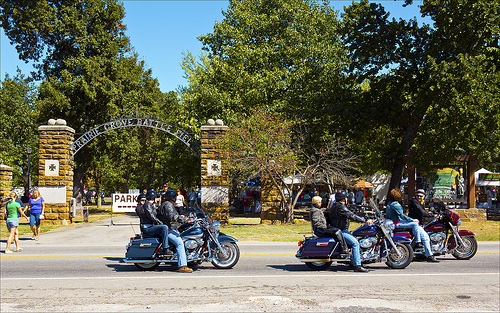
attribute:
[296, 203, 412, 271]
bike — hot looking, red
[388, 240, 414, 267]
front wheel — black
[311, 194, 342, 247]
lady — young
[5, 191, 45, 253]
girls — walking, young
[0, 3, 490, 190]
trees — large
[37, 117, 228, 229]
entrance — small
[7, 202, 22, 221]
shirt — green, blue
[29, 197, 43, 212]
shirt — blue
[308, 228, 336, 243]
saddlebag — blue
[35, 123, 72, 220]
column — stone, brick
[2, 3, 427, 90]
sky — clear, blue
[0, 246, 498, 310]
road — stained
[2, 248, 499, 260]
paint — yellow